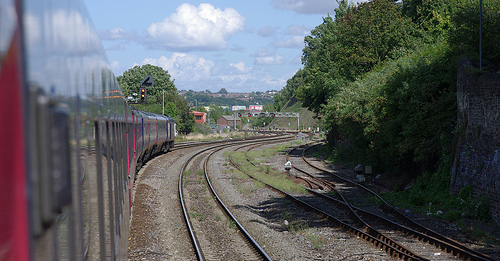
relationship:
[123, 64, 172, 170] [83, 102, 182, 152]
traffic light over train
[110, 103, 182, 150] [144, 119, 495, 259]
train curving tracks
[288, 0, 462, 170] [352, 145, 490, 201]
tree on embankment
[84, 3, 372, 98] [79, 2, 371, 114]
clouds in a sky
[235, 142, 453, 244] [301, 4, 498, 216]
shadow of trees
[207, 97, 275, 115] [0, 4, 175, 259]
billboards behind train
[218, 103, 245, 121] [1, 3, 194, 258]
building behind train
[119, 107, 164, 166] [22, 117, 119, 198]
doorways of train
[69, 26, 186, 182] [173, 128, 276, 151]
train on tracks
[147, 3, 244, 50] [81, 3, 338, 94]
cloud in sky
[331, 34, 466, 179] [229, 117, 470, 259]
shrubbery by tracks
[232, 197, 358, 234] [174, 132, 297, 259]
shadow on track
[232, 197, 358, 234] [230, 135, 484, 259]
shadow on track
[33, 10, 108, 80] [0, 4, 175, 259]
cloud reflection on train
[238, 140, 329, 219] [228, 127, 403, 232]
grass on tracks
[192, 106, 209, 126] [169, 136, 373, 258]
building by tracks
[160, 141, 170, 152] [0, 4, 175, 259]
wheel of train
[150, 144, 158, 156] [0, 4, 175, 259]
wheel of train